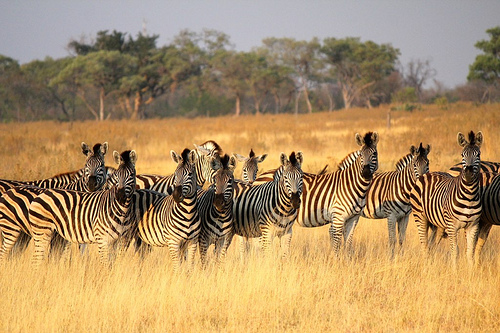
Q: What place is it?
A: It is a field.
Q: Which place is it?
A: It is a field.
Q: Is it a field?
A: Yes, it is a field.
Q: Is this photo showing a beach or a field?
A: It is showing a field.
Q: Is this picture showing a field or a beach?
A: It is showing a field.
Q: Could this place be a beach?
A: No, it is a field.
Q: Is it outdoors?
A: Yes, it is outdoors.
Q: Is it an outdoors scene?
A: Yes, it is outdoors.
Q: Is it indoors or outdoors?
A: It is outdoors.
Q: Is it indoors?
A: No, it is outdoors.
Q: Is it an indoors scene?
A: No, it is outdoors.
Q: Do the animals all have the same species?
A: Yes, all the animals are zebras.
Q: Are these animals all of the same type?
A: Yes, all the animals are zebras.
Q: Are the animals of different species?
A: No, all the animals are zebras.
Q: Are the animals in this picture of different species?
A: No, all the animals are zebras.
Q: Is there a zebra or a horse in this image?
A: Yes, there is a zebra.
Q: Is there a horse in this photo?
A: No, there are no horses.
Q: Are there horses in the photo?
A: No, there are no horses.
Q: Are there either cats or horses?
A: No, there are no horses or cats.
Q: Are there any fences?
A: No, there are no fences.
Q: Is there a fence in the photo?
A: No, there are no fences.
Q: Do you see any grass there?
A: Yes, there is grass.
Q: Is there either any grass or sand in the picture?
A: Yes, there is grass.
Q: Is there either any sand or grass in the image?
A: Yes, there is grass.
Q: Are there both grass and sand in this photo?
A: No, there is grass but no sand.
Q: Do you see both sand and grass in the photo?
A: No, there is grass but no sand.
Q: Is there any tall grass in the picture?
A: Yes, there is tall grass.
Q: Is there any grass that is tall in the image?
A: Yes, there is tall grass.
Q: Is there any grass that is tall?
A: Yes, there is grass that is tall.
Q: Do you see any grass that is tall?
A: Yes, there is grass that is tall.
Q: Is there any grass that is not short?
A: Yes, there is tall grass.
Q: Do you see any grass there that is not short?
A: Yes, there is tall grass.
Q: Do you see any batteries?
A: No, there are no batteries.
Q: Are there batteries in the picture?
A: No, there are no batteries.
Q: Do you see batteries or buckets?
A: No, there are no batteries or buckets.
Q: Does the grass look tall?
A: Yes, the grass is tall.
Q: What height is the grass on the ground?
A: The grass is tall.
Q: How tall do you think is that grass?
A: The grass is tall.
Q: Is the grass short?
A: No, the grass is tall.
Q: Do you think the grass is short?
A: No, the grass is tall.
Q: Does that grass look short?
A: No, the grass is tall.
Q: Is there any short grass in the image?
A: No, there is grass but it is tall.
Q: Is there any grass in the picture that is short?
A: No, there is grass but it is tall.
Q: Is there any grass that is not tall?
A: No, there is grass but it is tall.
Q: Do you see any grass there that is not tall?
A: No, there is grass but it is tall.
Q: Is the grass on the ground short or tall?
A: The grass is tall.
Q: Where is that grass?
A: The grass is on the ground.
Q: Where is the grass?
A: The grass is on the ground.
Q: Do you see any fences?
A: No, there are no fences.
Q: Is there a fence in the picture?
A: No, there are no fences.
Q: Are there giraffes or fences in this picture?
A: No, there are no fences or giraffes.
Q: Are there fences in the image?
A: No, there are no fences.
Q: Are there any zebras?
A: Yes, there are zebras.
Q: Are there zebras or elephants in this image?
A: Yes, there are zebras.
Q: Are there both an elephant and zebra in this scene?
A: No, there are zebras but no elephants.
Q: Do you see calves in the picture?
A: No, there are no calves.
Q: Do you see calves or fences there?
A: No, there are no calves or fences.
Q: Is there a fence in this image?
A: No, there are no fences.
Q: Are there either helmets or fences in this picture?
A: No, there are no fences or helmets.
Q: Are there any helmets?
A: No, there are no helmets.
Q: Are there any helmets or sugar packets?
A: No, there are no helmets or sugar packets.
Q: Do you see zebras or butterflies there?
A: Yes, there is a zebra.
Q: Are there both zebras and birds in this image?
A: No, there is a zebra but no birds.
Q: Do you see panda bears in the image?
A: No, there are no panda bears.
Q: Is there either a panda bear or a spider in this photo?
A: No, there are no panda bears or spiders.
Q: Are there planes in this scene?
A: No, there are no planes.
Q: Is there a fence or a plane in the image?
A: No, there are no airplanes or fences.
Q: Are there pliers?
A: No, there are no pliers.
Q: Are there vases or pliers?
A: No, there are no pliers or vases.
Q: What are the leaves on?
A: The leaves are on the tree.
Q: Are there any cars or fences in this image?
A: No, there are no fences or cars.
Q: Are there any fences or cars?
A: No, there are no fences or cars.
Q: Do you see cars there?
A: No, there are no cars.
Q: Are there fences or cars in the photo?
A: No, there are no cars or fences.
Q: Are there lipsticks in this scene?
A: No, there are no lipsticks.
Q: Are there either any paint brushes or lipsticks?
A: No, there are no lipsticks or paint brushes.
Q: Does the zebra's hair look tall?
A: Yes, the hair is tall.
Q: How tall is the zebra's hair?
A: The hair is tall.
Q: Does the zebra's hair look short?
A: No, the hair is tall.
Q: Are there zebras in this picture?
A: Yes, there is a zebra.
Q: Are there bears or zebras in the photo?
A: Yes, there is a zebra.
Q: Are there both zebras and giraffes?
A: No, there is a zebra but no giraffes.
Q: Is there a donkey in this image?
A: No, there are no donkeys.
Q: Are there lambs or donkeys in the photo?
A: No, there are no donkeys or lambs.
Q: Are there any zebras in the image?
A: Yes, there is a zebra.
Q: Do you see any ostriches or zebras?
A: Yes, there is a zebra.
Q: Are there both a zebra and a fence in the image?
A: No, there is a zebra but no fences.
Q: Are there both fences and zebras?
A: No, there is a zebra but no fences.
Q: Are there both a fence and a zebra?
A: No, there is a zebra but no fences.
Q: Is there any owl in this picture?
A: No, there are no owls.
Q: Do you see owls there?
A: No, there are no owls.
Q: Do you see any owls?
A: No, there are no owls.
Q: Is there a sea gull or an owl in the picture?
A: No, there are no owls or seagulls.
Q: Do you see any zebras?
A: Yes, there is a zebra.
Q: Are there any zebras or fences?
A: Yes, there is a zebra.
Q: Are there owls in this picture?
A: No, there are no owls.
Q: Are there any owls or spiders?
A: No, there are no owls or spiders.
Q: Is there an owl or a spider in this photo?
A: No, there are no owls or spiders.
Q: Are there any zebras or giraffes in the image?
A: Yes, there is a zebra.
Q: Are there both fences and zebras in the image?
A: No, there is a zebra but no fences.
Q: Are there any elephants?
A: No, there are no elephants.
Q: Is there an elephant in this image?
A: No, there are no elephants.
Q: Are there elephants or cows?
A: No, there are no elephants or cows.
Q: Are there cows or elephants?
A: No, there are no elephants or cows.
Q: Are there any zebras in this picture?
A: Yes, there is a zebra.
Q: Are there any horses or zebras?
A: Yes, there is a zebra.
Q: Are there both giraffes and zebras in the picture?
A: No, there is a zebra but no giraffes.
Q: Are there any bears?
A: No, there are no bears.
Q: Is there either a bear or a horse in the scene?
A: No, there are no bears or horses.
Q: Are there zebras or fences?
A: Yes, there is a zebra.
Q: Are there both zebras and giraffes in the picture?
A: No, there is a zebra but no giraffes.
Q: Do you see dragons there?
A: No, there are no dragons.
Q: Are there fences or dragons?
A: No, there are no dragons or fences.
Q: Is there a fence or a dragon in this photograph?
A: No, there are no dragons or fences.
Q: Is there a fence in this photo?
A: No, there are no fences.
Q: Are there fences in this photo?
A: No, there are no fences.